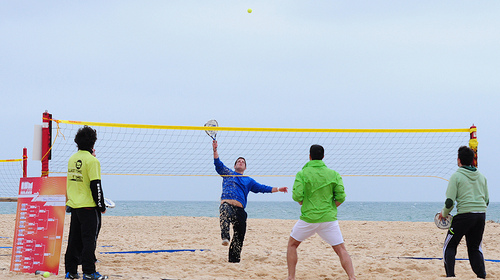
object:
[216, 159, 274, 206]
shirt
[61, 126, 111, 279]
man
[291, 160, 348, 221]
jacket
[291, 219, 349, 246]
shorts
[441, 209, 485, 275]
pants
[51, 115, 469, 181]
net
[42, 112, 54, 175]
pole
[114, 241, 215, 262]
boundary marker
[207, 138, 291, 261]
people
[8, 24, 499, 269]
tennis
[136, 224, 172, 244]
beach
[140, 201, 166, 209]
body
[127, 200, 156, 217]
water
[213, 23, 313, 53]
sky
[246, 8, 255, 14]
ball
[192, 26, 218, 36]
air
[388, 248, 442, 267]
line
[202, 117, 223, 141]
racket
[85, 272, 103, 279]
shoes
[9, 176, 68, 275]
sign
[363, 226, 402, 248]
sand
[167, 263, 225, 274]
ground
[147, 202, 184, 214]
ocean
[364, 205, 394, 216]
waves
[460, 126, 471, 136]
edge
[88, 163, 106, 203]
sleeve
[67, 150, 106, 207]
shirt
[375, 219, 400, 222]
border